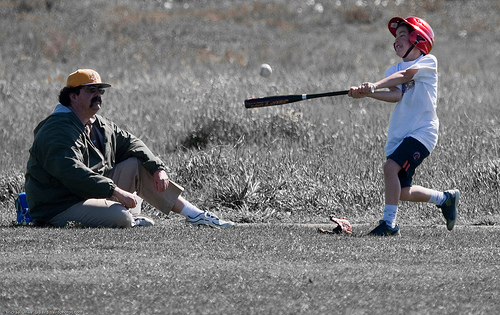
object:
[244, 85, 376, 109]
bat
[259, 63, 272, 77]
baseball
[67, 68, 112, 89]
hat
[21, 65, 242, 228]
man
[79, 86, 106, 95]
sunglasses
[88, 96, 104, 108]
mustache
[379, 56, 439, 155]
shirt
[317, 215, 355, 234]
glove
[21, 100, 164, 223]
jacket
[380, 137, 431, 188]
shorts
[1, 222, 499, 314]
grass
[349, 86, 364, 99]
hand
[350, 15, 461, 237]
boy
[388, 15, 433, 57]
batting helmet